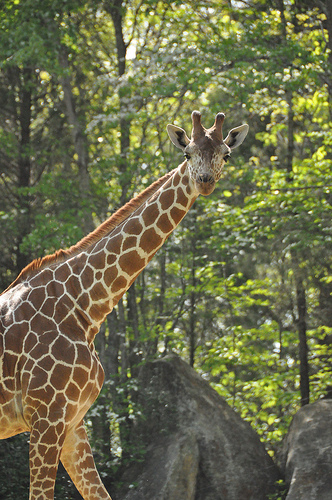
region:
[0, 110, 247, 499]
A giraffe standing tall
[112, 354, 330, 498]
Two big black boulders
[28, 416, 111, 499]
Front legs of the giraffe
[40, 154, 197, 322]
The long neck of the giraffe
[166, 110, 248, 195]
Head of the giraffe facing camera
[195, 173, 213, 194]
Black nose and brown mouth of the giraffe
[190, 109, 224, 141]
Two short horns covered with fur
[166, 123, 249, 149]
Two ears outstretched and erect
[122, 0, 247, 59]
sky visible a little through the tree leaves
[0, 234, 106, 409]
Beautiful pattern of white lines on the brown fur of the giraffe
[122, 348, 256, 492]
a gray big rock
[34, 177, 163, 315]
the giraffe is brown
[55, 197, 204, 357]
the giraffe is brown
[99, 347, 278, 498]
large gray boulder rock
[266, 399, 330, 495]
large grey boulder rock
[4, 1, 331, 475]
green trees in background in forest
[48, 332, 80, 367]
large brown spot bounded by cream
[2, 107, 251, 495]
large brown and cream spotted giraffe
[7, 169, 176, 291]
brown mane on back of giraffe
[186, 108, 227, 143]
two horns on top of giraffe's head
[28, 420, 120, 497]
two front visible legs of giraffe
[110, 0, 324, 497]
sun shining through trees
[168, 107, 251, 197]
face of giraffe facing camera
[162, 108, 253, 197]
A giraffe glances towards the camera.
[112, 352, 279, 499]
The rocks sit between the trees.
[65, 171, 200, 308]
The giraffe has a long neck.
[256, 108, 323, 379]
The trees stand tall.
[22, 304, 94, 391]
The giraffe's coat.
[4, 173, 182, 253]
The giraffe's mane.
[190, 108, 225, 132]
The giraffe has horns.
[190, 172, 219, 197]
The giraffe's snout.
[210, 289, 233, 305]
The sky peaks through the trees.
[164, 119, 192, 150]
The ear is perked up.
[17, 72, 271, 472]
an adult giraffe looking at the camera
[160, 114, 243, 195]
a head of an adult giraffe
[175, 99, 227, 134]
a horns of an adult giraffe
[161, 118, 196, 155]
a right ear of an adult giraffe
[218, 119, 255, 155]
a left ear of an adult giraffe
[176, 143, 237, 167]
a eyes of an adult giraffe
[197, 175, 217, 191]
a nose of an adult giraffe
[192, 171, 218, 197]
a mouth of an adult giraffe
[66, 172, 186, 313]
a neck of an adult giraffe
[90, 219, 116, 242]
a mane of an adult giraffe